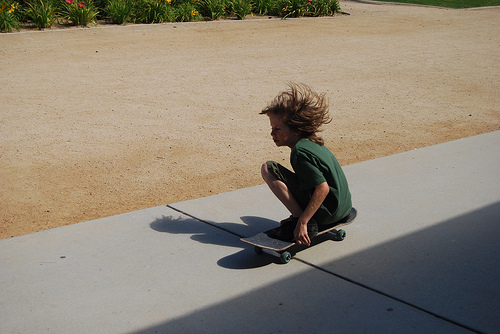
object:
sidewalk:
[357, 161, 480, 326]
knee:
[258, 158, 284, 182]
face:
[264, 113, 299, 148]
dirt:
[0, 28, 257, 200]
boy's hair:
[275, 92, 327, 124]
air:
[355, 2, 500, 178]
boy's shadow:
[160, 204, 251, 249]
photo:
[0, 1, 500, 333]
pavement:
[328, 182, 458, 307]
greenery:
[78, 6, 265, 24]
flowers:
[0, 0, 107, 26]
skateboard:
[238, 207, 366, 264]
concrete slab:
[336, 141, 484, 305]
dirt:
[339, 7, 493, 116]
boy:
[261, 98, 360, 228]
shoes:
[284, 211, 335, 247]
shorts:
[265, 170, 335, 239]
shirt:
[283, 132, 346, 229]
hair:
[275, 87, 330, 133]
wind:
[378, 19, 468, 133]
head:
[246, 91, 337, 147]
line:
[306, 255, 422, 310]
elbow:
[286, 158, 346, 226]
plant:
[116, 0, 213, 19]